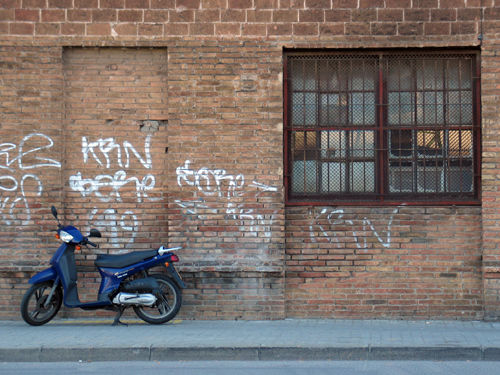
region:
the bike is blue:
[15, 224, 195, 331]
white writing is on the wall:
[75, 144, 144, 217]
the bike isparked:
[16, 215, 189, 322]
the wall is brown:
[222, 79, 274, 174]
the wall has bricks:
[199, 93, 250, 155]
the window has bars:
[290, 46, 481, 192]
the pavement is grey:
[238, 314, 395, 339]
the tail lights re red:
[169, 257, 181, 264]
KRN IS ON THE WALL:
[74, 132, 156, 164]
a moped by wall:
[17, 27, 497, 339]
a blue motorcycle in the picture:
[21, 203, 219, 335]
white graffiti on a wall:
[9, 123, 264, 223]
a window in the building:
[274, 42, 494, 227]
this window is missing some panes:
[270, 42, 484, 219]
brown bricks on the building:
[80, 74, 260, 129]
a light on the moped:
[43, 202, 108, 257]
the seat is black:
[92, 230, 180, 272]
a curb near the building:
[8, 327, 475, 369]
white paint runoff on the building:
[184, 234, 283, 290]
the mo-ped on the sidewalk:
[19, 197, 190, 329]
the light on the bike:
[49, 227, 85, 251]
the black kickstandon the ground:
[106, 305, 136, 327]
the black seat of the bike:
[95, 248, 161, 270]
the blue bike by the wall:
[17, 197, 191, 326]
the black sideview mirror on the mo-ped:
[46, 203, 64, 221]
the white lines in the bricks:
[1, 0, 498, 42]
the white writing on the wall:
[68, 126, 158, 205]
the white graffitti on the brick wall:
[169, 154, 281, 248]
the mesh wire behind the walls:
[286, 50, 477, 205]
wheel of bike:
[10, 278, 60, 327]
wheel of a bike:
[130, 268, 187, 324]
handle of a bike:
[110, 302, 133, 323]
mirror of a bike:
[36, 201, 68, 220]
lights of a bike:
[49, 223, 76, 243]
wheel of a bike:
[81, 223, 106, 246]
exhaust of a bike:
[111, 287, 167, 312]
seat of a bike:
[87, 238, 161, 280]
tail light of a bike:
[165, 247, 182, 264]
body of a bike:
[62, 249, 157, 304]